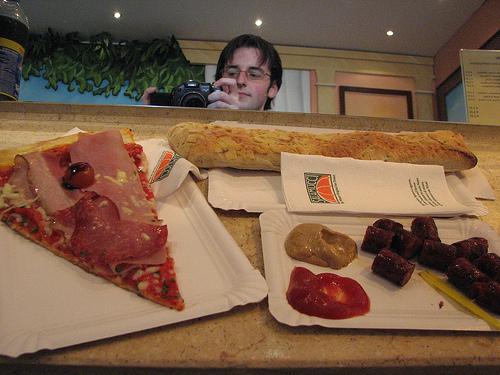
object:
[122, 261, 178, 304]
toppings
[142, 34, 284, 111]
glasses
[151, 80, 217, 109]
camera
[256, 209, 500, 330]
plate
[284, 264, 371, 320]
dipping sauce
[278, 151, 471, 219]
napkin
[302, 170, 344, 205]
logo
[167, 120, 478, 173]
baguette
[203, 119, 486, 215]
plate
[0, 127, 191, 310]
pizza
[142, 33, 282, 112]
man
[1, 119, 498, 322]
food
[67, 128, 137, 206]
meat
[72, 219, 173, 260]
meat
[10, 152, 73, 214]
meat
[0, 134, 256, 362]
tray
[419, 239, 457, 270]
sausage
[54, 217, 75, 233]
cheese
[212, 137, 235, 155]
cheese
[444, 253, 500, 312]
sausage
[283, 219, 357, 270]
condiments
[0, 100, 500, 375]
table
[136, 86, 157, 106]
hand